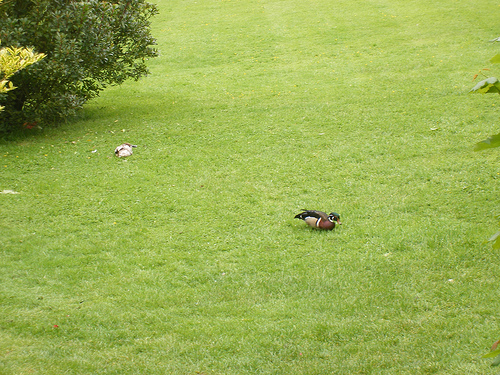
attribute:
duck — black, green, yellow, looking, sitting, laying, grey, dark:
[309, 205, 341, 234]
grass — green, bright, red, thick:
[325, 114, 366, 162]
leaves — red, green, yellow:
[92, 117, 113, 139]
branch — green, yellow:
[80, 13, 121, 52]